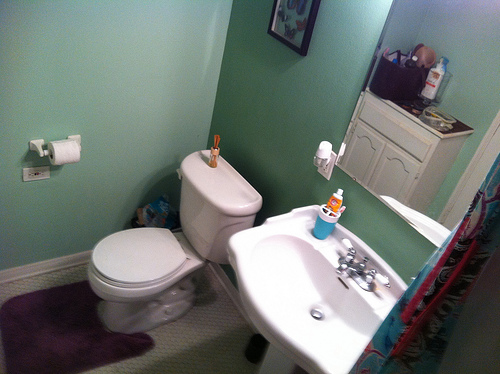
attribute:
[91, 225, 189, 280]
lid — white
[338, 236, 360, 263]
faucet — chrome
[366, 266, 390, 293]
faucet — chrome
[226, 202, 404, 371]
sink — white, porcelain, pedestal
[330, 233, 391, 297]
tap — shiny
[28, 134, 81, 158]
paper holder — white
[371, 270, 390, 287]
handle — ceramic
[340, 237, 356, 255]
handle — ceramic